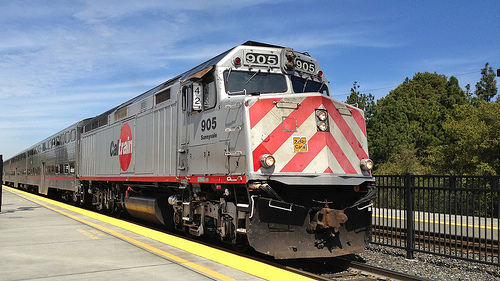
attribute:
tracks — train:
[299, 259, 433, 279]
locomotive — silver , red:
[9, 41, 374, 256]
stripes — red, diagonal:
[250, 99, 374, 182]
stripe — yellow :
[3, 185, 326, 280]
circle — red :
[117, 124, 136, 167]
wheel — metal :
[218, 208, 234, 245]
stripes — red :
[247, 92, 371, 179]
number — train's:
[196, 114, 220, 134]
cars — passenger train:
[2, 114, 84, 204]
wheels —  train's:
[162, 193, 249, 248]